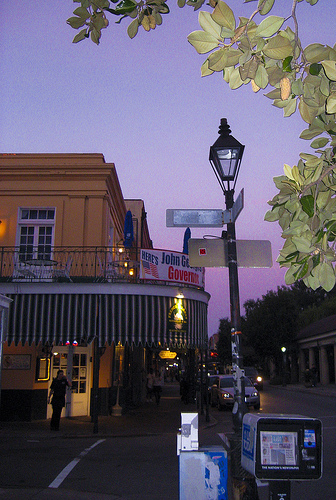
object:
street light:
[206, 111, 253, 433]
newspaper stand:
[236, 403, 325, 499]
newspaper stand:
[172, 407, 232, 500]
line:
[47, 434, 107, 485]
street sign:
[163, 203, 229, 230]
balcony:
[2, 241, 211, 293]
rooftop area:
[0, 145, 181, 287]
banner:
[0, 286, 211, 350]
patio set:
[1, 240, 140, 283]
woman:
[42, 360, 73, 435]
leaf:
[301, 194, 315, 218]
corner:
[171, 398, 335, 499]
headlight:
[221, 388, 234, 402]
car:
[208, 370, 261, 415]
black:
[46, 370, 71, 432]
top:
[172, 403, 202, 456]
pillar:
[89, 339, 101, 435]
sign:
[162, 293, 191, 333]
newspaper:
[259, 425, 299, 468]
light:
[174, 290, 186, 329]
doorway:
[44, 330, 95, 429]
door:
[47, 339, 94, 420]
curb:
[178, 363, 217, 430]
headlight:
[249, 389, 261, 404]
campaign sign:
[136, 244, 205, 292]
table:
[21, 251, 61, 282]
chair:
[48, 244, 78, 284]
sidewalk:
[0, 370, 218, 437]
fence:
[0, 240, 206, 296]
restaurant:
[0, 150, 211, 423]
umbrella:
[121, 207, 138, 273]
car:
[202, 374, 214, 389]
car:
[239, 364, 266, 393]